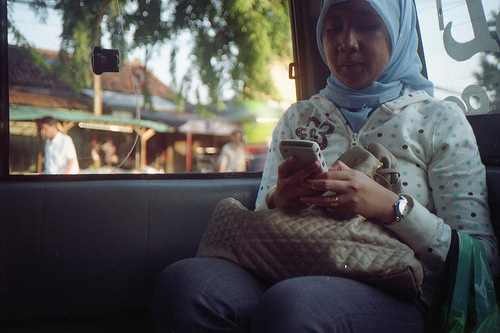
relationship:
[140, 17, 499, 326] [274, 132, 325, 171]
woman holding cell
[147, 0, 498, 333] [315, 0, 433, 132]
woman wearing burka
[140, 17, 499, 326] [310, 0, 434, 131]
woman wearing burka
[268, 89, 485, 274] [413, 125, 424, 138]
hoodie with polka dot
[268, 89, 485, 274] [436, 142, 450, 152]
hoodie with polka dot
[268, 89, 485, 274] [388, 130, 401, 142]
hoodie with polka dot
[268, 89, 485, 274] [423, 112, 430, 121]
hoodie with polka dot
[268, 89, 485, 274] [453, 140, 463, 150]
hoodie with polka dot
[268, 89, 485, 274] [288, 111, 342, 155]
hoodie with flower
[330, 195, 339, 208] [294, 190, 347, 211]
ring on finger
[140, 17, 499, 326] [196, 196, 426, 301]
woman holding purse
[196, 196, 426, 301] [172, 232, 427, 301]
purse on lap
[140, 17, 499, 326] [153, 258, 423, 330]
woman wearing grey pants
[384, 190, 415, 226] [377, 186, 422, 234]
watch on wrist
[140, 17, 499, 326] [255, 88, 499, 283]
woman wearing hoodie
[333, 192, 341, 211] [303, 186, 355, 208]
ring on finger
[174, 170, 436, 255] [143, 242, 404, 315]
purse sitting in lap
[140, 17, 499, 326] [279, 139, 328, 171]
woman holding cellphone